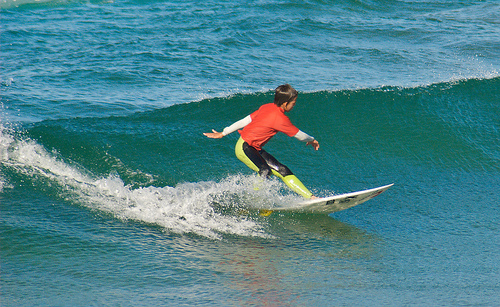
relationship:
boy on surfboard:
[203, 84, 320, 202] [255, 182, 397, 210]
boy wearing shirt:
[203, 84, 320, 202] [235, 102, 299, 151]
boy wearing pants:
[203, 84, 320, 202] [235, 135, 310, 206]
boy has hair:
[203, 84, 320, 202] [273, 84, 298, 108]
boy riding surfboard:
[203, 84, 320, 202] [255, 182, 397, 210]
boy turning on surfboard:
[203, 84, 320, 202] [255, 182, 397, 210]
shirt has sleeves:
[235, 102, 299, 151] [218, 115, 314, 144]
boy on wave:
[203, 84, 320, 202] [1, 73, 498, 236]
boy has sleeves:
[203, 84, 320, 202] [218, 115, 314, 144]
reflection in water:
[209, 210, 380, 304] [5, 3, 491, 306]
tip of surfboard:
[358, 181, 398, 200] [255, 182, 397, 210]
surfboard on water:
[255, 182, 397, 210] [5, 3, 491, 306]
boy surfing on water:
[203, 84, 320, 202] [5, 3, 491, 306]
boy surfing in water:
[203, 84, 320, 202] [5, 3, 491, 306]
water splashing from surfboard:
[5, 3, 491, 306] [255, 182, 397, 210]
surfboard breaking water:
[255, 182, 397, 210] [1, 122, 300, 249]